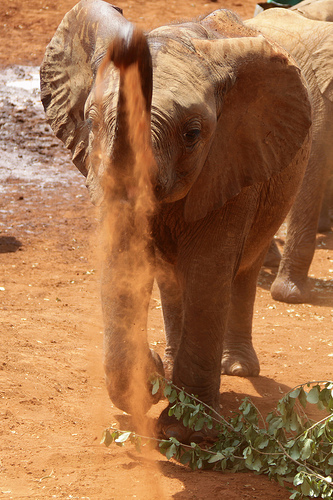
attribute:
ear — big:
[38, 2, 109, 181]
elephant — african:
[41, 0, 313, 439]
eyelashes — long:
[78, 115, 92, 128]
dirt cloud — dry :
[93, 66, 162, 479]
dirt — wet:
[3, 86, 65, 206]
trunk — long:
[90, 19, 177, 207]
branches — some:
[102, 368, 331, 498]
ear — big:
[183, 33, 310, 225]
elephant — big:
[43, 23, 330, 467]